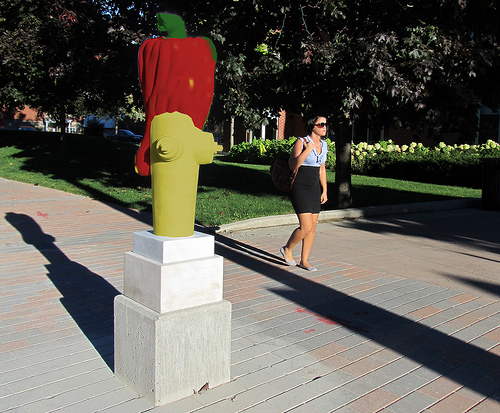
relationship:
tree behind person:
[221, 6, 493, 208] [270, 115, 329, 273]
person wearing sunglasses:
[270, 115, 329, 273] [313, 120, 328, 130]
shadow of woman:
[54, 172, 287, 266] [270, 117, 325, 272]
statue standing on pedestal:
[133, 12, 223, 238] [114, 226, 234, 398]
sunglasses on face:
[313, 118, 327, 128] [316, 116, 328, 136]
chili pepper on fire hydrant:
[135, 10, 215, 174] [133, 18, 225, 243]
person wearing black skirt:
[270, 115, 329, 273] [289, 165, 322, 214]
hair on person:
[292, 111, 330, 137] [270, 115, 329, 273]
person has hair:
[270, 115, 329, 273] [302, 111, 316, 126]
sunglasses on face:
[314, 122, 327, 128] [316, 113, 327, 138]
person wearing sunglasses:
[270, 115, 329, 273] [314, 122, 327, 128]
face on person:
[316, 113, 327, 138] [270, 115, 329, 273]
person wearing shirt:
[274, 105, 335, 277] [295, 134, 330, 169]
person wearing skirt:
[270, 115, 329, 273] [277, 162, 347, 217]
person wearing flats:
[270, 115, 329, 273] [276, 246, 318, 274]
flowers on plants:
[350, 138, 499, 160] [225, 134, 498, 188]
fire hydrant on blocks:
[133, 11, 223, 237] [157, 242, 217, 382]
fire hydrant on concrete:
[133, 11, 223, 237] [169, 275, 211, 303]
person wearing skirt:
[270, 115, 329, 273] [285, 165, 322, 215]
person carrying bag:
[270, 115, 329, 273] [270, 137, 308, 192]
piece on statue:
[157, 12, 217, 60] [133, 12, 223, 238]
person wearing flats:
[270, 115, 329, 273] [269, 241, 324, 274]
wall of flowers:
[351, 137, 498, 174] [352, 137, 498, 157]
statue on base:
[133, 12, 223, 238] [111, 230, 233, 405]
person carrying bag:
[270, 115, 329, 273] [265, 141, 298, 190]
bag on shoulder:
[265, 141, 298, 190] [297, 134, 311, 150]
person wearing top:
[270, 115, 329, 273] [296, 135, 327, 167]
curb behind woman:
[214, 197, 381, 237] [283, 109, 330, 270]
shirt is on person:
[293, 129, 330, 169] [270, 115, 329, 273]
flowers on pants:
[350, 138, 499, 160] [272, 162, 329, 219]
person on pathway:
[270, 115, 329, 273] [1, 174, 498, 408]